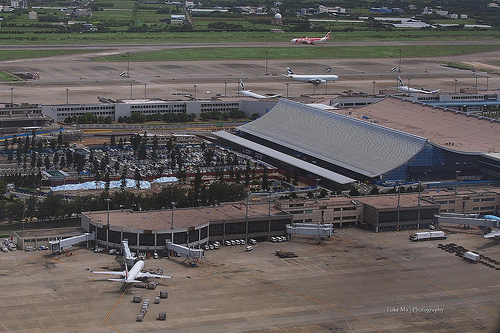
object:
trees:
[34, 156, 44, 173]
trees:
[131, 139, 151, 158]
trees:
[164, 163, 177, 169]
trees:
[22, 190, 43, 220]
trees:
[201, 23, 228, 34]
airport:
[1, 2, 499, 332]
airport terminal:
[0, 93, 498, 126]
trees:
[1, 194, 20, 228]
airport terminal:
[42, 183, 499, 263]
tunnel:
[283, 222, 333, 241]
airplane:
[92, 258, 173, 282]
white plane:
[278, 68, 335, 85]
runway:
[10, 78, 269, 93]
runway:
[24, 289, 424, 326]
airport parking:
[2, 137, 276, 180]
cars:
[231, 240, 236, 246]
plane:
[393, 84, 437, 97]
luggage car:
[134, 308, 150, 321]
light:
[67, 86, 69, 90]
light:
[9, 88, 16, 92]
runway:
[0, 37, 498, 49]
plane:
[289, 30, 331, 45]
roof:
[240, 92, 498, 189]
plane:
[236, 82, 281, 98]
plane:
[285, 63, 344, 84]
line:
[101, 290, 128, 323]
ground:
[262, 274, 400, 301]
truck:
[411, 231, 440, 240]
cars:
[270, 237, 277, 242]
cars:
[249, 239, 257, 244]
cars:
[246, 246, 254, 251]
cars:
[225, 240, 231, 245]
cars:
[212, 242, 219, 249]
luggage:
[142, 299, 148, 308]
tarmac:
[0, 229, 499, 330]